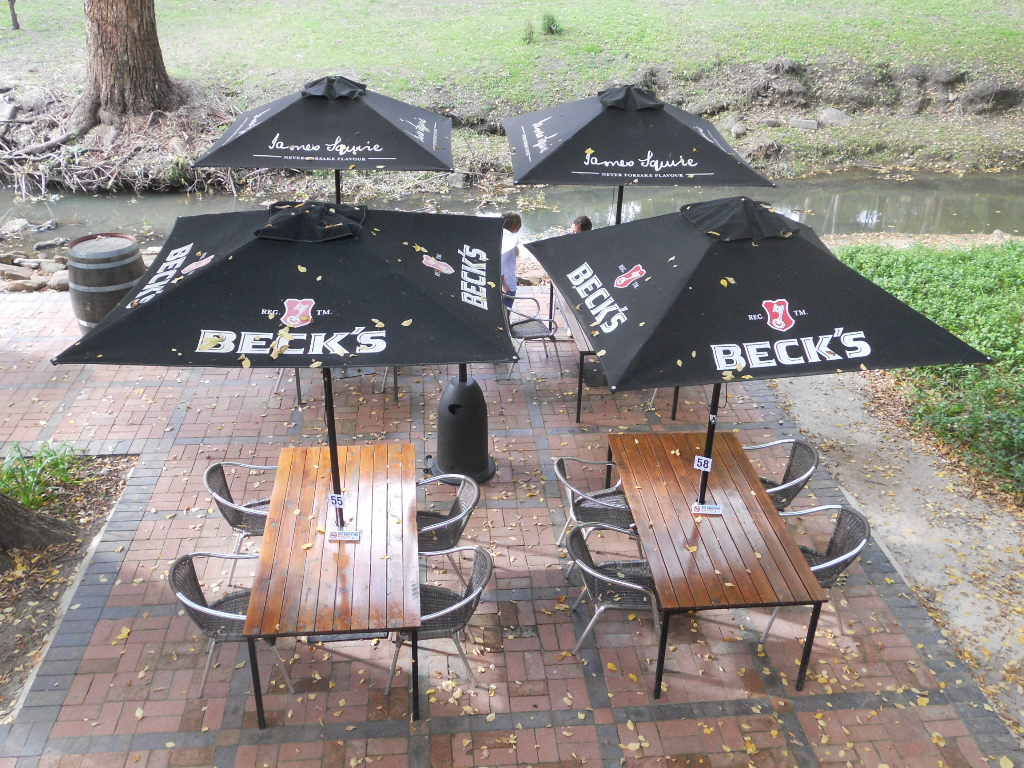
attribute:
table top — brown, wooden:
[249, 445, 422, 640]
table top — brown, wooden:
[606, 426, 833, 617]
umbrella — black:
[48, 199, 511, 550]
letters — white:
[192, 320, 394, 355]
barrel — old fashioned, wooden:
[61, 219, 165, 366]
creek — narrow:
[0, 381, 811, 448]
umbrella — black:
[525, 195, 990, 397]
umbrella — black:
[48, 212, 515, 362]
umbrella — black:
[510, 80, 778, 189]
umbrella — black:
[188, 72, 457, 166]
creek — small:
[9, 162, 1021, 245]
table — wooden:
[600, 430, 840, 699]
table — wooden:
[238, 435, 422, 725]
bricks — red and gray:
[2, 351, 1012, 755]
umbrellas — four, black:
[190, 74, 448, 206]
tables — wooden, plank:
[240, 437, 426, 721]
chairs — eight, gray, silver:
[168, 435, 869, 727]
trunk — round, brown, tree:
[77, 8, 184, 121]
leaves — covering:
[0, 426, 42, 476]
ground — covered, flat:
[19, 260, 1020, 768]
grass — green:
[773, 215, 1011, 458]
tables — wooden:
[244, 430, 828, 733]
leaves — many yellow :
[705, 702, 960, 716]